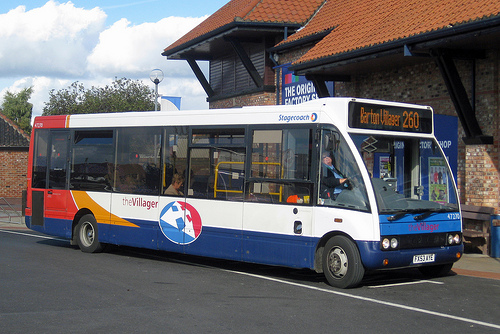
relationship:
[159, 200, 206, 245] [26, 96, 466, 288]
arrows on bus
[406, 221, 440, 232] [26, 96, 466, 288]
letters on bus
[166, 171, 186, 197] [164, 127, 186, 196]
woman in window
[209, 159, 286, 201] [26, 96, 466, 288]
handrail on bus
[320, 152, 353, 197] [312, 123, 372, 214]
driver in window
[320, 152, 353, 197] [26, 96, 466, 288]
driver on bus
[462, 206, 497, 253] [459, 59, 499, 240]
bench on wall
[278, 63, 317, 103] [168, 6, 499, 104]
sign on building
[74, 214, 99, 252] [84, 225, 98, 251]
wheel has part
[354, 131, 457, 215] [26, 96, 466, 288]
window on bus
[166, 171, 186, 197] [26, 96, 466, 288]
woman on bus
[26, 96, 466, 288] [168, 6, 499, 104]
bus parked by building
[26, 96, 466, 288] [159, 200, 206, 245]
bus has circle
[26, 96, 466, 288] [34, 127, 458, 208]
bus has windows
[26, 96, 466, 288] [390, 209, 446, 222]
bus has wipers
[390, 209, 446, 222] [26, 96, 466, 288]
wipers on front of bus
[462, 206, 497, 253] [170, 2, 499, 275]
bench in front o store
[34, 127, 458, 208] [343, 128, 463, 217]
windows next to window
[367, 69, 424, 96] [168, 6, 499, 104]
part of building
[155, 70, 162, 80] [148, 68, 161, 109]
part of light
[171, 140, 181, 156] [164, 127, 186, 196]
part of window